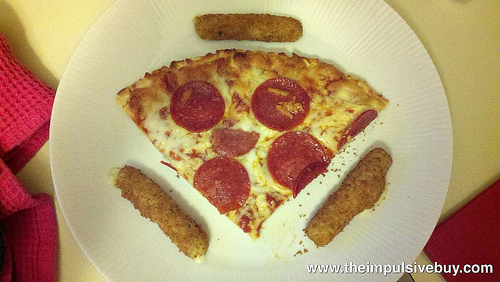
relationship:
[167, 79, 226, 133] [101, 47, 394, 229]
pepperoni on pizza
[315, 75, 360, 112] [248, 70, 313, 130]
cheese on pepperoni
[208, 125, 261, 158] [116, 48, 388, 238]
pepperoni on pizza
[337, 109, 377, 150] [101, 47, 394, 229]
pepperoni on pizza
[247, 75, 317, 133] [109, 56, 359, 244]
pepperoni on pizza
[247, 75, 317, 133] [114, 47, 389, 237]
pepperoni on pizza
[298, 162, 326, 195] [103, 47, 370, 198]
pepperoni on pizza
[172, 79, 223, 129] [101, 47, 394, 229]
pepperoni on pizza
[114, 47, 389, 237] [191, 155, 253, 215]
pizza on pepperoni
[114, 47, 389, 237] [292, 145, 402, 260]
pizza on mozzarella stick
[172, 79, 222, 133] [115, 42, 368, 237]
pepperoni on pizza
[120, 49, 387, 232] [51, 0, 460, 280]
food on plate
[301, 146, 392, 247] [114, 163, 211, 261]
mozzarella stick next mozzarella stick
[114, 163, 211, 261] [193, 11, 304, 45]
mozzarella stick next mozzarella stick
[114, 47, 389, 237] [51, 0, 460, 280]
pizza on plate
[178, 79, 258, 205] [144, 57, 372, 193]
pepperoni on pizza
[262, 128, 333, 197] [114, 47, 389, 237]
pepperoni on pizza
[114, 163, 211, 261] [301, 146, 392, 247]
mozzarella stick next to mozzarella stick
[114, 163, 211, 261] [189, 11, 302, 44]
mozzarella stick next to cheese stick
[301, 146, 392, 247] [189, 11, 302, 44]
mozzarella stick next to cheese stick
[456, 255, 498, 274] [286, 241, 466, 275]
.com on address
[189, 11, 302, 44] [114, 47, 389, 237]
cheese stick above a pizza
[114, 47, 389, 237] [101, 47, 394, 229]
pizza of pizza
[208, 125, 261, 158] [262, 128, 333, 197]
pepperoni of pepperoni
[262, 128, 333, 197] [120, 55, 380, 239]
pepperoni buried under cheese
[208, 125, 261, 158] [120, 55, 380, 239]
pepperoni buried under cheese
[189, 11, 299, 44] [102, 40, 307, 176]
cheese stick above pizza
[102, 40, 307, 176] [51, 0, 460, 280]
pizza on plate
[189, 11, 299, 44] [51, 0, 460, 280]
cheese stick on plate